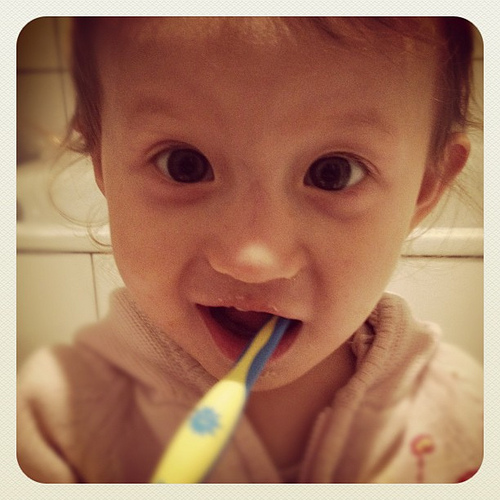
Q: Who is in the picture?
A: A girl.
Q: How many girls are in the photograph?
A: One.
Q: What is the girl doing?
A: Brushing her teeth.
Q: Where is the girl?
A: In the bathroom.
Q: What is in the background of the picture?
A: A bathtub.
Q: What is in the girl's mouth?
A: A toothbrush.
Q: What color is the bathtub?
A: White.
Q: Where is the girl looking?
A: At the camera.